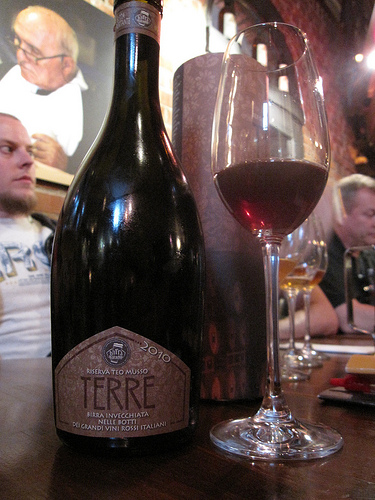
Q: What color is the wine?
A: Red.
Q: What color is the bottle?
A: Black.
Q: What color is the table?
A: Brown.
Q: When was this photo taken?
A: During the night.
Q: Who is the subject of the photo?
A: The wine.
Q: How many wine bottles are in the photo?
A: One.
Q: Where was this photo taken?
A: At a restaurant.